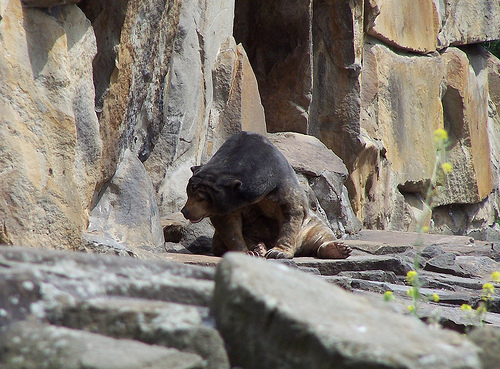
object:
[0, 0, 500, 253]
wall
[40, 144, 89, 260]
stone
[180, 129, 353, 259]
bear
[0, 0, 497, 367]
rock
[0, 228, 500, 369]
flower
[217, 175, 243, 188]
ear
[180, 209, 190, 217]
nose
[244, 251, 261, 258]
hand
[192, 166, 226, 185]
hair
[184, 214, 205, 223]
mouth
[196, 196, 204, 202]
eye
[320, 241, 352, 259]
paw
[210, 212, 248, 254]
leg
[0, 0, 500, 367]
zoo